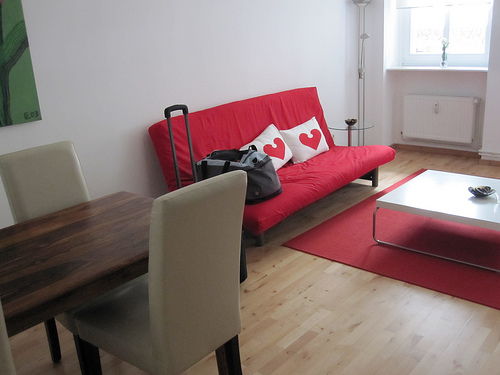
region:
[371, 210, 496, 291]
shadow cast on the floor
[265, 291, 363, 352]
lines on the wood floor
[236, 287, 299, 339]
small spots on the floor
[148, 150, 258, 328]
back of tan chair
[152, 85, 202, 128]
black handle on luggage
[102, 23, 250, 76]
light blue wall in the background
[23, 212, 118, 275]
dark brown mahogany table top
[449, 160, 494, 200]
ashtray on table top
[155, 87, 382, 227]
red sofa bed against wall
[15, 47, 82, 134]
edge of green painting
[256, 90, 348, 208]
this is a sofa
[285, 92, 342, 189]
the sofa is empty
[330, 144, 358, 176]
the sofa is red in color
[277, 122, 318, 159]
the pillows are two in number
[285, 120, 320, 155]
the pillow is white in color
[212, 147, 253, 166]
this is a bag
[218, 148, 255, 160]
the bag is on the sofa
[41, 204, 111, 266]
the table is clean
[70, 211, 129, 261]
the table is wooden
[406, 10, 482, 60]
the window is closed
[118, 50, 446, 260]
a big red couch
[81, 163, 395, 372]
a brown chair in background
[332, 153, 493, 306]
a red rug on ground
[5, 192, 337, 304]
a wooden table in background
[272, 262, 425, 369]
clear wooden flooring on floor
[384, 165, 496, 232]
a sliver table in background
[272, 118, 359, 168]
a red heart on couch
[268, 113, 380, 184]
a white and red pillow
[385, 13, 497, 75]
a bright big window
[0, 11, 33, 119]
a painting on the wall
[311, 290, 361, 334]
part of a floor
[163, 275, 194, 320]
part of a chair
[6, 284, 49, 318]
edge of a table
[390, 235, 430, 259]
part of a stand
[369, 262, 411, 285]
edge of a carpet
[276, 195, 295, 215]
part of a chair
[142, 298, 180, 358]
edge of a chair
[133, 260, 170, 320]
edge of a chair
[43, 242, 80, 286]
top of a table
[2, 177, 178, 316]
The table is wooden